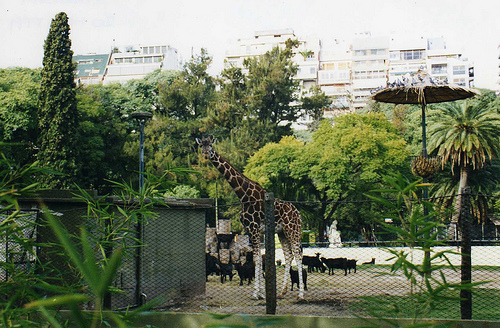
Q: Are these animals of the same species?
A: No, there are both giraffes and goats.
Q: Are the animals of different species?
A: Yes, they are giraffes and goats.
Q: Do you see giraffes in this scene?
A: Yes, there is a giraffe.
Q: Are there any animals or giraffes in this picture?
A: Yes, there is a giraffe.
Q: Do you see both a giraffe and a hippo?
A: No, there is a giraffe but no hippoes.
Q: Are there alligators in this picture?
A: No, there are no alligators.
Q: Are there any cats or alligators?
A: No, there are no alligators or cats.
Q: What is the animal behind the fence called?
A: The animal is a giraffe.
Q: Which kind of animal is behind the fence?
A: The animal is a giraffe.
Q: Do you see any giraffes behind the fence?
A: Yes, there is a giraffe behind the fence.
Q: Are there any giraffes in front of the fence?
A: No, the giraffe is behind the fence.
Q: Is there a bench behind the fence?
A: No, there is a giraffe behind the fence.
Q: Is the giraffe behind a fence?
A: Yes, the giraffe is behind a fence.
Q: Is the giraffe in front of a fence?
A: No, the giraffe is behind a fence.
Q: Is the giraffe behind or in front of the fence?
A: The giraffe is behind the fence.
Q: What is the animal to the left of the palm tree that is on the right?
A: The animal is a giraffe.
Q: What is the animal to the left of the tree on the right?
A: The animal is a giraffe.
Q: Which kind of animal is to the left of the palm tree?
A: The animal is a giraffe.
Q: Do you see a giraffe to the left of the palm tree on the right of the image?
A: Yes, there is a giraffe to the left of the palm.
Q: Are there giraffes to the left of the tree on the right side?
A: Yes, there is a giraffe to the left of the palm.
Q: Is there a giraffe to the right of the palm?
A: No, the giraffe is to the left of the palm.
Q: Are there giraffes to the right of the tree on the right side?
A: No, the giraffe is to the left of the palm.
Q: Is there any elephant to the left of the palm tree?
A: No, there is a giraffe to the left of the palm tree.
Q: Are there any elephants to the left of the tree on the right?
A: No, there is a giraffe to the left of the palm tree.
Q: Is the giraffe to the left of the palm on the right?
A: Yes, the giraffe is to the left of the palm.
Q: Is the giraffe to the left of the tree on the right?
A: Yes, the giraffe is to the left of the palm.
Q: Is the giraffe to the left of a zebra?
A: No, the giraffe is to the left of the palm.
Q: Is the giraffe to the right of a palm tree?
A: No, the giraffe is to the left of a palm tree.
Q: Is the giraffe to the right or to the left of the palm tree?
A: The giraffe is to the left of the palm tree.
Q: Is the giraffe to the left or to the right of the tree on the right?
A: The giraffe is to the left of the palm tree.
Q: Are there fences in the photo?
A: Yes, there is a fence.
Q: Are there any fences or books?
A: Yes, there is a fence.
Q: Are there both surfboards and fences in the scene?
A: No, there is a fence but no surfboards.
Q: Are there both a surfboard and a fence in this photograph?
A: No, there is a fence but no surfboards.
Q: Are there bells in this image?
A: No, there are no bells.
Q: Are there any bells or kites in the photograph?
A: No, there are no bells or kites.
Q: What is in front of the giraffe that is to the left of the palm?
A: The fence is in front of the giraffe.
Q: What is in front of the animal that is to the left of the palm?
A: The fence is in front of the giraffe.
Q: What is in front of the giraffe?
A: The fence is in front of the giraffe.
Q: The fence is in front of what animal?
A: The fence is in front of the giraffe.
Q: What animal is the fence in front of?
A: The fence is in front of the giraffe.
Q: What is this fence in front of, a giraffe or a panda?
A: The fence is in front of a giraffe.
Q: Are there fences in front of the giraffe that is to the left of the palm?
A: Yes, there is a fence in front of the giraffe.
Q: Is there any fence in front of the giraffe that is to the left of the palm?
A: Yes, there is a fence in front of the giraffe.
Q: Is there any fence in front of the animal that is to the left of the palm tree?
A: Yes, there is a fence in front of the giraffe.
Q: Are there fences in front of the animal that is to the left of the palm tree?
A: Yes, there is a fence in front of the giraffe.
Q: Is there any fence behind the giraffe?
A: No, the fence is in front of the giraffe.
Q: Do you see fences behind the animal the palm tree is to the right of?
A: No, the fence is in front of the giraffe.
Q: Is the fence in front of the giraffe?
A: Yes, the fence is in front of the giraffe.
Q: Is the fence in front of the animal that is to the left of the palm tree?
A: Yes, the fence is in front of the giraffe.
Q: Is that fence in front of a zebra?
A: No, the fence is in front of the giraffe.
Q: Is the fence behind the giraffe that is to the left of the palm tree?
A: No, the fence is in front of the giraffe.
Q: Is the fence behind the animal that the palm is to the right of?
A: No, the fence is in front of the giraffe.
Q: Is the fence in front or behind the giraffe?
A: The fence is in front of the giraffe.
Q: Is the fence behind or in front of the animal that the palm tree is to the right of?
A: The fence is in front of the giraffe.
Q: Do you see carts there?
A: No, there are no carts.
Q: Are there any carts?
A: No, there are no carts.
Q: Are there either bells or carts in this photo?
A: No, there are no carts or bells.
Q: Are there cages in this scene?
A: No, there are no cages.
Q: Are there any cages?
A: No, there are no cages.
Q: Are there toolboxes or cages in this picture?
A: No, there are no cages or toolboxes.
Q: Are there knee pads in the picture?
A: No, there are no knee pads.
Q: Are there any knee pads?
A: No, there are no knee pads.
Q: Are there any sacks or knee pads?
A: No, there are no knee pads or sacks.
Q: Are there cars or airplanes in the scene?
A: No, there are no cars or airplanes.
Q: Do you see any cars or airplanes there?
A: No, there are no cars or airplanes.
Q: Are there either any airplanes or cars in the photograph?
A: No, there are no cars or airplanes.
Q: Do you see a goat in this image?
A: Yes, there are goats.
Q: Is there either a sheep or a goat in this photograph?
A: Yes, there are goats.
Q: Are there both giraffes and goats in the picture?
A: Yes, there are both goats and a giraffe.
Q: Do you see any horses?
A: No, there are no horses.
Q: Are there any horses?
A: No, there are no horses.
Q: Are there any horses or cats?
A: No, there are no horses or cats.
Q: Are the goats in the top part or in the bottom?
A: The goats are in the bottom of the image.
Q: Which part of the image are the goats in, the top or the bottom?
A: The goats are in the bottom of the image.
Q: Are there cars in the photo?
A: No, there are no cars.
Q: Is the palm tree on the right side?
A: Yes, the palm tree is on the right of the image.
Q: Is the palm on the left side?
A: No, the palm is on the right of the image.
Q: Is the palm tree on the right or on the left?
A: The palm tree is on the right of the image.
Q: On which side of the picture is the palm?
A: The palm is on the right of the image.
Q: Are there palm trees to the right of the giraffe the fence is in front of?
A: Yes, there is a palm tree to the right of the giraffe.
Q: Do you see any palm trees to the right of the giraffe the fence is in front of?
A: Yes, there is a palm tree to the right of the giraffe.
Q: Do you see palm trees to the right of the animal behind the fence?
A: Yes, there is a palm tree to the right of the giraffe.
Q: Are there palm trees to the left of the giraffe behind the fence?
A: No, the palm tree is to the right of the giraffe.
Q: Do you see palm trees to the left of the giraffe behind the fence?
A: No, the palm tree is to the right of the giraffe.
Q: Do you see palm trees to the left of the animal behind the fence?
A: No, the palm tree is to the right of the giraffe.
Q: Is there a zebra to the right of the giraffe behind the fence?
A: No, there is a palm tree to the right of the giraffe.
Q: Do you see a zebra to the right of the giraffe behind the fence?
A: No, there is a palm tree to the right of the giraffe.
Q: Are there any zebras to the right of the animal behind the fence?
A: No, there is a palm tree to the right of the giraffe.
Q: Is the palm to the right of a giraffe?
A: Yes, the palm is to the right of a giraffe.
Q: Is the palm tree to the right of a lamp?
A: No, the palm tree is to the right of a giraffe.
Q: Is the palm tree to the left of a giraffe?
A: No, the palm tree is to the right of a giraffe.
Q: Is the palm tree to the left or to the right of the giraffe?
A: The palm tree is to the right of the giraffe.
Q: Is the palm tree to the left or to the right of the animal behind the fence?
A: The palm tree is to the right of the giraffe.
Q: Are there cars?
A: No, there are no cars.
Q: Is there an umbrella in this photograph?
A: Yes, there is an umbrella.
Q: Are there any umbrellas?
A: Yes, there is an umbrella.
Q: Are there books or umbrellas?
A: Yes, there is an umbrella.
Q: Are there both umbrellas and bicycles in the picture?
A: No, there is an umbrella but no bicycles.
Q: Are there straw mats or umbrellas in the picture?
A: Yes, there is a straw umbrella.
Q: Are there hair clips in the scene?
A: No, there are no hair clips.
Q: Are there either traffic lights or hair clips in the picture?
A: No, there are no hair clips or traffic lights.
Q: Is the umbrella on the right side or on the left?
A: The umbrella is on the right of the image.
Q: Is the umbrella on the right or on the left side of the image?
A: The umbrella is on the right of the image.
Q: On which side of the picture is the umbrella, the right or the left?
A: The umbrella is on the right of the image.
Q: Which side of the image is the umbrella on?
A: The umbrella is on the right of the image.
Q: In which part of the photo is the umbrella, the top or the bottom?
A: The umbrella is in the top of the image.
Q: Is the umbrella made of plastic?
A: No, the umbrella is made of straw.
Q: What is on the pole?
A: The umbrella is on the pole.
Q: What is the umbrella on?
A: The umbrella is on the pole.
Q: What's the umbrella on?
A: The umbrella is on the pole.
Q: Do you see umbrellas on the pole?
A: Yes, there is an umbrella on the pole.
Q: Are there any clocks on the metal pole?
A: No, there is an umbrella on the pole.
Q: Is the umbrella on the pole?
A: Yes, the umbrella is on the pole.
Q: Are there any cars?
A: No, there are no cars.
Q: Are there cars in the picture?
A: No, there are no cars.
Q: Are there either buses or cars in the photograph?
A: No, there are no cars or buses.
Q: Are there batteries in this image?
A: No, there are no batteries.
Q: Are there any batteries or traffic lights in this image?
A: No, there are no batteries or traffic lights.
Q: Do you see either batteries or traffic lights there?
A: No, there are no batteries or traffic lights.